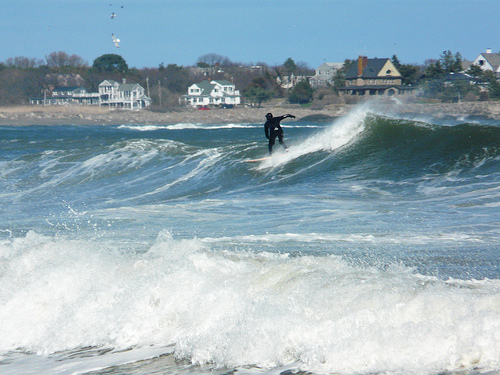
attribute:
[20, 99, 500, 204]
wave — large, high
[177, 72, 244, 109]
house — in background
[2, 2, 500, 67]
sky — blue